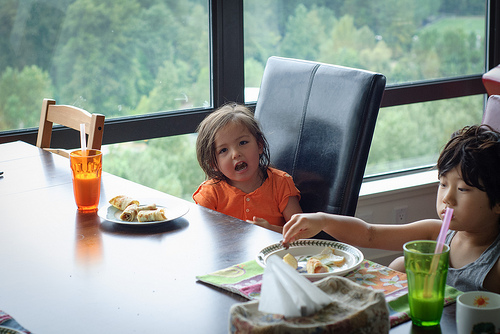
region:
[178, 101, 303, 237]
Young girl wearing orange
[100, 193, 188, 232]
Plate with food on table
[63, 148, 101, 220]
Orange glass on table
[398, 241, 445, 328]
Green glass on table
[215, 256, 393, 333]
Box of tissue on table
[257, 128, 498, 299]
Young boy reaching for food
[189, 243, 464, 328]
Colorful placemat on table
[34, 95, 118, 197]
Wooden chair pulled up to table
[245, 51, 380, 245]
Black leather chair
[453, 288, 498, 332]
White coffee mug on table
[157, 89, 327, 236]
little girl sitting on chair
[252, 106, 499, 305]
little boy sitting on chair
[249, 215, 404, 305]
white plate on place mat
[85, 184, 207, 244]
white plate on table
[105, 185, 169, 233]
pancakes on plate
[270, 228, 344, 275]
pieces of pancake on table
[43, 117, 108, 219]
orange cup on table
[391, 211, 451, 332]
green cup on table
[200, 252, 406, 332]
tissue box on the table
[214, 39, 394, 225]
black leather chair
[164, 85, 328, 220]
kid on a chair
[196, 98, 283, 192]
head of a kid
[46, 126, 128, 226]
drink on the table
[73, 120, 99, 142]
straw in the drink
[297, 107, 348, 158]
reflection on the seat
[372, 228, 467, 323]
green glass on table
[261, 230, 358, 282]
plate on the table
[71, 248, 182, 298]
light hitting the table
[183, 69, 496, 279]
two kids in the photo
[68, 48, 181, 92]
trees outside the window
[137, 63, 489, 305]
kids sitting at the table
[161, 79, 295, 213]
the girl is looking at the camera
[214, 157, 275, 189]
the mouth is open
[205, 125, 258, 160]
the eyes are open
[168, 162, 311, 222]
the girl is wearing a short sleeved shirt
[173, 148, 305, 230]
the shirt is orange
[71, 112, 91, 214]
a straw in the glass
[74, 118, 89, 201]
the straw is white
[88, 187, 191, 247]
food on a plate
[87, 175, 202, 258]
the plate is white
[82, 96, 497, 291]
two children seated at table eating finger foods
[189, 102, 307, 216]
little girl with brown hair wearing orange shirt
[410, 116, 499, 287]
young boy wearing gray tank top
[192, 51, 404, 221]
little girl in high back adult chair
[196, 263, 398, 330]
tissue box with handcrafted cover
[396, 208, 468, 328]
green glass filled one fourth way with milk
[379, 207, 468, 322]
green glass with pink straw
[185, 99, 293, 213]
little girl not eating, paying attention to camera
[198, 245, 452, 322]
handmade placemat under male child's dinner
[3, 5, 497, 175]
large window overlooking trees